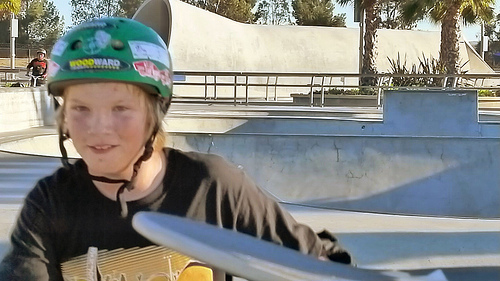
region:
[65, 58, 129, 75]
logo on the helmet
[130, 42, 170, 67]
logo on the helmet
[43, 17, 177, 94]
helmet on the boy's hand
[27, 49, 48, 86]
boy on the bike next to the wall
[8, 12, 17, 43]
electrical box on the pole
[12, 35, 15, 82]
pole attached to the electrical box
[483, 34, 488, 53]
electrical box attached to a pole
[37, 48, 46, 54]
helmet on the boy's head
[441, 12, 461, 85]
tree trunk in the foliage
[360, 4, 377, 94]
tree trunk in the foliage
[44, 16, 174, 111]
Green helmet on a boy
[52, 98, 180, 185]
Strap on a helmet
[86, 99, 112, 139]
Nose on a boy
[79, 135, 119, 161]
Mouth on a boy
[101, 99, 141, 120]
Eye on a boy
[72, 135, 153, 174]
Chin on a boy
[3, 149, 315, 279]
Black shirt on a boy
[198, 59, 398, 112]
Rail at a skatepark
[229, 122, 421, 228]
Gray cement skateboard ramp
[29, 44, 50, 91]
Person on a bike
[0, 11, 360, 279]
Boy with a black shirt on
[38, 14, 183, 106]
Green helmet on the boy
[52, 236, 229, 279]
Gold picture on the boys shirt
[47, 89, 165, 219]
Black straps attached to the helmet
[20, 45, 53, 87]
Boy in the background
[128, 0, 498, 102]
Concrete tunnel behind the boy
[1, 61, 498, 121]
Metal railing behind the boy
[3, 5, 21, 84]
Sign on a pole to the left of the boys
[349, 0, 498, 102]
Two large palm trees in front of the tunnel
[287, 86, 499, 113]
Concrete planter the trees are in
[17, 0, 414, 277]
boy at a skatepark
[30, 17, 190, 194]
young boy wearing a helmet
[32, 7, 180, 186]
boy wearing a green helmet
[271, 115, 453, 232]
cement skate ramp at a skating park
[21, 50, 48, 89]
young man on a scooter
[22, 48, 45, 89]
young boy riding a bike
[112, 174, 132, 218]
black strap of a helmet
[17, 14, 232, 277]
boy is wearing a black and yellow tee with a green helmet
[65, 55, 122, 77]
sticker affixed to helmet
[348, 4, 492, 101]
trees and vegetation in the skate park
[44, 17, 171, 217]
the helmet on the boy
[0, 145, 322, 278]
the black shirt on the boy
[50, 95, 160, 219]
the strap hanging under the boy's face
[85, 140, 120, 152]
the smile on the boy's face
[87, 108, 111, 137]
the nose on the boy's face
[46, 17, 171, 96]
the stickers on the boy's helmet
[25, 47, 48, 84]
the boy in the background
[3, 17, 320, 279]
the boy wearing a helmet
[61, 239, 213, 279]
the design on the boy's shirt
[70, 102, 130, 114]
the eyes on the boy's face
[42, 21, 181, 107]
green helmet of boy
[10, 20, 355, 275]
boy wearing black shirt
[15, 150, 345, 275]
black colored shirt on boy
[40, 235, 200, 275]
yellow colored logo on shirt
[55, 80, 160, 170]
face of boy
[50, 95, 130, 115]
eyes on boy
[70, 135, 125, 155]
mouth on boy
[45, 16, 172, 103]
the helmet is green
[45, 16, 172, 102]
the stickers on the helmet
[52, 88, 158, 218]
the straps are black